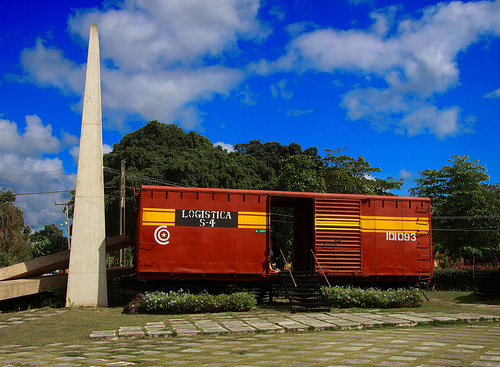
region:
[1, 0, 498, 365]
image is part of boxcar museum on santa clara island, cuba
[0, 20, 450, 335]
museum is in honor of che guevara+18 more revolutionaries+molotov+a dead bulldozer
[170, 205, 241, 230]
'logistica s-4' on train car turned into museum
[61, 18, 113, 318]
a definitely pointy monument [even though point's dulled]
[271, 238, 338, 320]
stairway into boxcar museum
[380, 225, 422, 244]
'101093', in white, @ right on boxcar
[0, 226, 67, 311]
this, i believe, is the bottom of another statue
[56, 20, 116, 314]
monument is probably made of marble, bit weatherbeaten at tip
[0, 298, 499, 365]
interesting mosaicized walkway on the grass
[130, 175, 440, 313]
derailed train car, in more ways than one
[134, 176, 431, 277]
red and yellow train car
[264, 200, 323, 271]
open door of train car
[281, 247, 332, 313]
stairs to train car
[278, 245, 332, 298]
railing of the stairs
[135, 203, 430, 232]
yellow stripes on train car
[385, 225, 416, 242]
white lettering on red background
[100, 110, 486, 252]
trees behind the train car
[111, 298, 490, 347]
pathway in front of train car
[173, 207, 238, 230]
white lettering on black background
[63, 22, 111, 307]
white monument next to train car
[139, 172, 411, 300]
red and yellow car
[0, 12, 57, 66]
white clouds in blue sky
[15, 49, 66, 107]
white clouds in blue sky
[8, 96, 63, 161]
white clouds in blue sky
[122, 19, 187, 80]
white clouds in blue sky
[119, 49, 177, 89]
white clouds in blue sky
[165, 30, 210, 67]
white clouds in blue sky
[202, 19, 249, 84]
white clouds in blue sky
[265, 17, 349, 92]
white clouds in blue sky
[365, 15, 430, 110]
white clouds in blue sky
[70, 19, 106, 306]
long white tower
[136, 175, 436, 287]
red and yellow boxcar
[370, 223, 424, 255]
numbers 101093 on the boxcar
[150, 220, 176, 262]
star logo on the boxcar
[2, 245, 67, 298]
slabs of cement near the tower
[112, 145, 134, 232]
elecrical wires on the pole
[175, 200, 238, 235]
logistica S-4 logo on the side of the boxcar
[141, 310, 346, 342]
gray stone path on the grass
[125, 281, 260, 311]
flowering bushes nest to boxcar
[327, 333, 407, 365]
gray squares on the ground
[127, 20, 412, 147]
bright blue sky with white clouds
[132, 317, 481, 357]
grass covered stone path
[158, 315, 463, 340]
stone pathway leading to truck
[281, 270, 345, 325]
black stairs on truck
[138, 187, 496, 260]
red and yellow trailer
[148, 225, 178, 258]
white target spot on trailer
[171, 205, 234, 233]
Logistca S-4 on trialer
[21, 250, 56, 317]
two pieces of large wood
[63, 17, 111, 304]
pointy cement colored structure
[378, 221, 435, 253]
101093 written on trailer